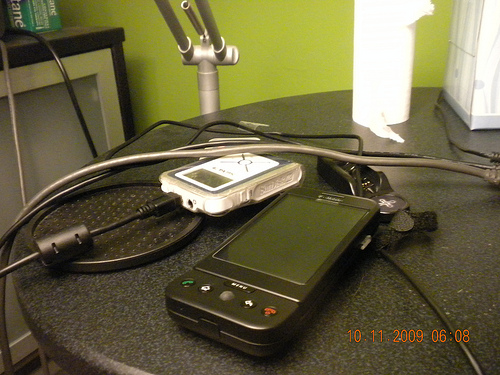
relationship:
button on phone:
[175, 273, 197, 289] [164, 180, 387, 360]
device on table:
[148, 143, 298, 217] [11, 83, 483, 368]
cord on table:
[10, 140, 487, 224] [11, 83, 483, 368]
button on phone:
[256, 301, 283, 321] [164, 180, 387, 360]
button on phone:
[176, 273, 200, 293] [164, 180, 387, 360]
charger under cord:
[33, 182, 198, 272] [3, 192, 181, 273]